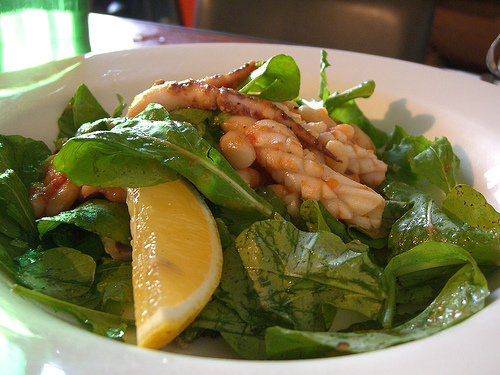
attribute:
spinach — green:
[46, 101, 270, 213]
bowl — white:
[30, 22, 499, 106]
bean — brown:
[208, 116, 278, 183]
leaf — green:
[224, 206, 405, 336]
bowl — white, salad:
[8, 36, 481, 372]